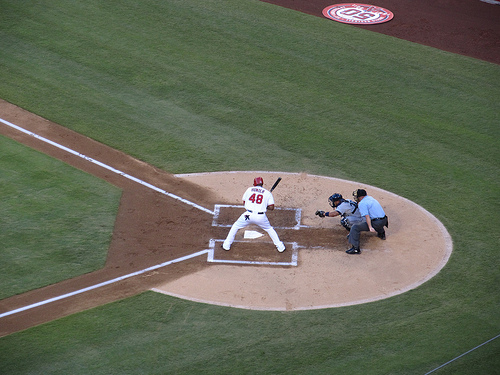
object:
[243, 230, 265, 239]
home plate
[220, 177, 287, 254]
baseball player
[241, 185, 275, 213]
shirt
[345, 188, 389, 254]
umpire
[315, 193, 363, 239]
catcher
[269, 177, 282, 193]
bat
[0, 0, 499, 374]
baseball field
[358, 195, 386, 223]
shirt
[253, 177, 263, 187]
helmet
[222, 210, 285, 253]
pants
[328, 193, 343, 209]
helmet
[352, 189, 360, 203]
mask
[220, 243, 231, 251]
shoe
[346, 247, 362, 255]
shoe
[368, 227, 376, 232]
hand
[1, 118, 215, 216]
line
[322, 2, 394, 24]
object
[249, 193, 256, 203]
number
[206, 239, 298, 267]
batter's box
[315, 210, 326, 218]
glove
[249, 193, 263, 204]
number 48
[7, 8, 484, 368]
baseball game